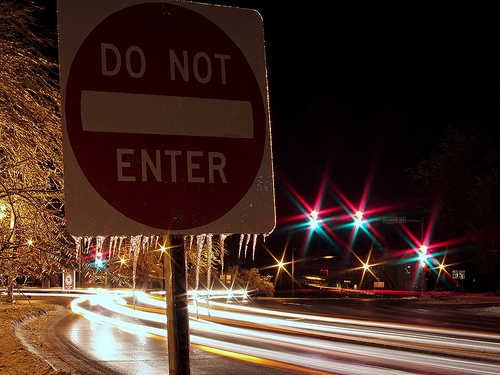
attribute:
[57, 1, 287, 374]
sign — red, white, square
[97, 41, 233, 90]
text — white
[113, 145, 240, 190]
text — white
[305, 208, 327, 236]
light — blue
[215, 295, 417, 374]
road — bright, white, wet, shiny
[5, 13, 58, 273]
tree — bare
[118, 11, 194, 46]
circle — red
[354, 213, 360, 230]
light — red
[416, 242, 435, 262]
light — red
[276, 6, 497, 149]
sky — black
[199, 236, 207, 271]
icicle — white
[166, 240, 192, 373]
pole — metal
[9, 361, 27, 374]
grass — brown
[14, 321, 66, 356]
curb — gray